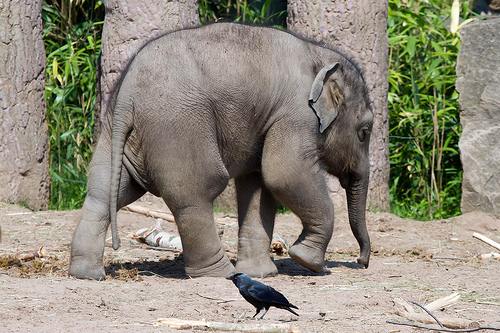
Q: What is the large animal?
A: Elephant.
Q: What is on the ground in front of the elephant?
A: Bird.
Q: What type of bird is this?
A: Crow.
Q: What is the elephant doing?
A: Walking.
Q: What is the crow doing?
A: Standing.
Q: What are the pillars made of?
A: Stone.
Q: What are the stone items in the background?
A: Pillars.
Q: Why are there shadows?
A: Sunny.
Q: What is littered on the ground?
A: Branches.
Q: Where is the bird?
A: On the ground.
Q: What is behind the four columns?
A: Plants.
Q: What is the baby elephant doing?
A: Walking.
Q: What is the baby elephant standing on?
A: Dirt.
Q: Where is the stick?
A: On the ground.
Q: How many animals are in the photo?
A: 2.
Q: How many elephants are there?
A: 1.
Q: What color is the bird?
A: Black.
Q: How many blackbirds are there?
A: 1.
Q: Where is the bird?
A: On the ground.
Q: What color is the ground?
A: Gray.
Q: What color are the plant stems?
A: Brown.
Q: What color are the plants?
A: Green.